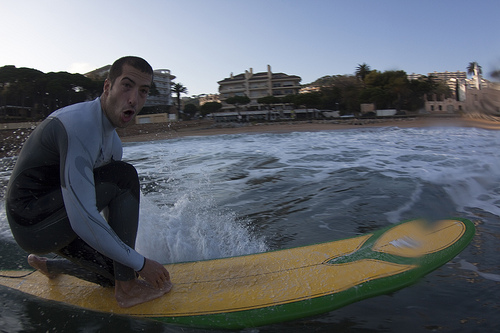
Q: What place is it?
A: It is an ocean.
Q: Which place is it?
A: It is an ocean.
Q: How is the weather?
A: It is clear.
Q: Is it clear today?
A: Yes, it is clear.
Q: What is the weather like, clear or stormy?
A: It is clear.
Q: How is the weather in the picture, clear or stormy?
A: It is clear.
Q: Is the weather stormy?
A: No, it is clear.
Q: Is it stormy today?
A: No, it is clear.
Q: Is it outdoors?
A: Yes, it is outdoors.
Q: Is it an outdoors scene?
A: Yes, it is outdoors.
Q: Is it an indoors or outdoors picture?
A: It is outdoors.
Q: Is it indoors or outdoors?
A: It is outdoors.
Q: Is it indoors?
A: No, it is outdoors.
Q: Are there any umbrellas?
A: No, there are no umbrellas.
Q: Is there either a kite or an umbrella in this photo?
A: No, there are no umbrellas or kites.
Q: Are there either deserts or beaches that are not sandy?
A: No, there is a beach but it is sandy.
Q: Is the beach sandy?
A: Yes, the beach is sandy.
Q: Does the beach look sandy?
A: Yes, the beach is sandy.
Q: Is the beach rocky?
A: No, the beach is sandy.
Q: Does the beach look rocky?
A: No, the beach is sandy.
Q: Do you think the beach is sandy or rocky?
A: The beach is sandy.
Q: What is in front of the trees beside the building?
A: The beach is in front of the trees.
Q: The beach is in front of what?
A: The beach is in front of the trees.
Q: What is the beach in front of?
A: The beach is in front of the trees.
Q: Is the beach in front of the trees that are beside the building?
A: Yes, the beach is in front of the trees.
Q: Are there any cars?
A: No, there are no cars.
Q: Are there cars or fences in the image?
A: No, there are no cars or fences.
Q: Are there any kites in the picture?
A: No, there are no kites.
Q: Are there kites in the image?
A: No, there are no kites.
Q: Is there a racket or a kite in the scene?
A: No, there are no kites or rackets.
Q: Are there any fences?
A: No, there are no fences.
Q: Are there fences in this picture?
A: No, there are no fences.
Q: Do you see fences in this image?
A: No, there are no fences.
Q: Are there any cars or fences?
A: No, there are no fences or cars.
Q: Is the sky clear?
A: Yes, the sky is clear.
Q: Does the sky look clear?
A: Yes, the sky is clear.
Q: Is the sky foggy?
A: No, the sky is clear.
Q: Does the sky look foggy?
A: No, the sky is clear.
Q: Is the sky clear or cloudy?
A: The sky is clear.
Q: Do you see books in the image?
A: No, there are no books.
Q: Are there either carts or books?
A: No, there are no books or carts.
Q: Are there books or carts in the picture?
A: No, there are no books or carts.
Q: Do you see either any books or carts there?
A: No, there are no books or carts.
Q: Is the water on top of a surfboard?
A: Yes, the water is on top of a surfboard.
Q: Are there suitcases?
A: No, there are no suitcases.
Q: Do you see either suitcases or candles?
A: No, there are no suitcases or candles.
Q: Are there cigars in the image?
A: No, there are no cigars.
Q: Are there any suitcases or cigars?
A: No, there are no cigars or suitcases.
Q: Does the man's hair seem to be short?
A: Yes, the hair is short.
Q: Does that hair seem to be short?
A: Yes, the hair is short.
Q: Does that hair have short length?
A: Yes, the hair is short.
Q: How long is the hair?
A: The hair is short.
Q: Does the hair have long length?
A: No, the hair is short.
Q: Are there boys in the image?
A: No, there are no boys.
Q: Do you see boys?
A: No, there are no boys.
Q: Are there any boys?
A: No, there are no boys.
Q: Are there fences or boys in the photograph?
A: No, there are no boys or fences.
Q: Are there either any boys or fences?
A: No, there are no boys or fences.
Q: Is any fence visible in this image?
A: No, there are no fences.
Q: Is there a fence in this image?
A: No, there are no fences.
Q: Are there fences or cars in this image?
A: No, there are no fences or cars.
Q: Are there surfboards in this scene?
A: Yes, there is a surfboard.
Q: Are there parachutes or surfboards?
A: Yes, there is a surfboard.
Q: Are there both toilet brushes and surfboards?
A: No, there is a surfboard but no toilet brushes.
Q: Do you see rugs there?
A: No, there are no rugs.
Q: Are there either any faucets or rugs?
A: No, there are no rugs or faucets.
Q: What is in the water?
A: The surfboard is in the water.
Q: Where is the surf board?
A: The surf board is in the water.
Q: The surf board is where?
A: The surf board is in the water.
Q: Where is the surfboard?
A: The surf board is in the water.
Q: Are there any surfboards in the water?
A: Yes, there is a surfboard in the water.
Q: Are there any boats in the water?
A: No, there is a surfboard in the water.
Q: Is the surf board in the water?
A: Yes, the surf board is in the water.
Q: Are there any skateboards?
A: No, there are no skateboards.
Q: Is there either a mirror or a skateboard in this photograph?
A: No, there are no skateboards or mirrors.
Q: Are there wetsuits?
A: Yes, there is a wetsuit.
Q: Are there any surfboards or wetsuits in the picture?
A: Yes, there is a wetsuit.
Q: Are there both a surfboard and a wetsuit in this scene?
A: Yes, there are both a wetsuit and a surfboard.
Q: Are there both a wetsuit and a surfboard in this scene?
A: Yes, there are both a wetsuit and a surfboard.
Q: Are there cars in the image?
A: No, there are no cars.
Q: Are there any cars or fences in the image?
A: No, there are no cars or fences.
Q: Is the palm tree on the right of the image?
A: Yes, the palm tree is on the right of the image.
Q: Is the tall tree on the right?
A: Yes, the palm tree is on the right of the image.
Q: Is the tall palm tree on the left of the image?
A: No, the palm tree is on the right of the image.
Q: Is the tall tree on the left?
A: No, the palm tree is on the right of the image.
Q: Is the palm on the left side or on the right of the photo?
A: The palm is on the right of the image.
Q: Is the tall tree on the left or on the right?
A: The palm is on the right of the image.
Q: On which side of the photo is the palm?
A: The palm is on the right of the image.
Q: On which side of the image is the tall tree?
A: The palm is on the right of the image.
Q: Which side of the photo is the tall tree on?
A: The palm is on the right of the image.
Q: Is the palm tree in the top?
A: Yes, the palm tree is in the top of the image.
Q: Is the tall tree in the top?
A: Yes, the palm tree is in the top of the image.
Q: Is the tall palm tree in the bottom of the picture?
A: No, the palm is in the top of the image.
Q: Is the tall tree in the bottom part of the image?
A: No, the palm is in the top of the image.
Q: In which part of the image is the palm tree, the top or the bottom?
A: The palm tree is in the top of the image.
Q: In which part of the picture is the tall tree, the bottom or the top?
A: The palm tree is in the top of the image.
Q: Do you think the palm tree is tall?
A: Yes, the palm tree is tall.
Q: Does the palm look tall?
A: Yes, the palm is tall.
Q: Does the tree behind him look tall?
A: Yes, the palm is tall.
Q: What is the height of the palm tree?
A: The palm tree is tall.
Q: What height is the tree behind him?
A: The palm tree is tall.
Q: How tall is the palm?
A: The palm is tall.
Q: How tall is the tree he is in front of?
A: The palm is tall.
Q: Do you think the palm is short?
A: No, the palm is tall.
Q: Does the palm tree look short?
A: No, the palm tree is tall.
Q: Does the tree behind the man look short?
A: No, the palm tree is tall.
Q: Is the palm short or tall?
A: The palm is tall.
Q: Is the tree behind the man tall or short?
A: The palm is tall.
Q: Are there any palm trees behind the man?
A: Yes, there is a palm tree behind the man.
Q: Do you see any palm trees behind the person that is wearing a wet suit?
A: Yes, there is a palm tree behind the man.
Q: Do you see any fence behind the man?
A: No, there is a palm tree behind the man.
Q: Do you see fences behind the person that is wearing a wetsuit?
A: No, there is a palm tree behind the man.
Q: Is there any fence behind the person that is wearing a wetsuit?
A: No, there is a palm tree behind the man.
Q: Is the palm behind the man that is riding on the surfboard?
A: Yes, the palm is behind the man.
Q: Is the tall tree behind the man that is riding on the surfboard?
A: Yes, the palm is behind the man.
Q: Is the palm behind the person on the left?
A: Yes, the palm is behind the man.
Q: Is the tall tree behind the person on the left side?
A: Yes, the palm is behind the man.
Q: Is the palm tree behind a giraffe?
A: No, the palm tree is behind the man.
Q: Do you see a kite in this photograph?
A: No, there are no kites.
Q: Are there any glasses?
A: No, there are no glasses.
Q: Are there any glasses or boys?
A: No, there are no glasses or boys.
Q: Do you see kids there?
A: No, there are no kids.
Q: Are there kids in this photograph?
A: No, there are no kids.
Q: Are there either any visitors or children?
A: No, there are no children or visitors.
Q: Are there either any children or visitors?
A: No, there are no children or visitors.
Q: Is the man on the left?
A: Yes, the man is on the left of the image.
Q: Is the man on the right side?
A: No, the man is on the left of the image.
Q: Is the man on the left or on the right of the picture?
A: The man is on the left of the image.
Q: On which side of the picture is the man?
A: The man is on the left of the image.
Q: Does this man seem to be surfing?
A: Yes, the man is surfing.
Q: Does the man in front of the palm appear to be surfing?
A: Yes, the man is surfing.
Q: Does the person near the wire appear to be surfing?
A: Yes, the man is surfing.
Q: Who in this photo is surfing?
A: The man is surfing.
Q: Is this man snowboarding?
A: No, the man is surfing.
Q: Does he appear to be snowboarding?
A: No, the man is surfing.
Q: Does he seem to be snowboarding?
A: No, the man is surfing.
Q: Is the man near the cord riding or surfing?
A: The man is surfing.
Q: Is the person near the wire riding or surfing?
A: The man is surfing.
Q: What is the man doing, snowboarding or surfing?
A: The man is surfing.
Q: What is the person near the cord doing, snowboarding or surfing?
A: The man is surfing.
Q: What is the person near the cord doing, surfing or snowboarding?
A: The man is surfing.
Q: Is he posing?
A: Yes, the man is posing.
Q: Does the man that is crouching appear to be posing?
A: Yes, the man is posing.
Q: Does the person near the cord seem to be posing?
A: Yes, the man is posing.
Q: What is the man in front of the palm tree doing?
A: The man is posing.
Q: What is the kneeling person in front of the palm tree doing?
A: The man is posing.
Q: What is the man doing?
A: The man is posing.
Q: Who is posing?
A: The man is posing.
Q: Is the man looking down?
A: No, the man is posing.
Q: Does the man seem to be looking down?
A: No, the man is posing.